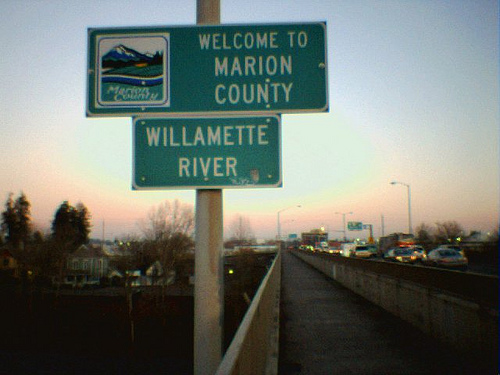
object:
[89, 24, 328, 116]
sign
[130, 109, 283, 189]
sign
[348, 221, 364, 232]
sign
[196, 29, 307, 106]
writing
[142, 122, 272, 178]
writing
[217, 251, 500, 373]
bridge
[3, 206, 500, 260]
horizon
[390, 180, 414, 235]
street light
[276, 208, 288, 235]
street light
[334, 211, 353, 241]
street light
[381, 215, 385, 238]
street light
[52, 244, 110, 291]
house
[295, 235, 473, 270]
cars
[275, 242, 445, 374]
sidewalk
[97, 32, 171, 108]
picture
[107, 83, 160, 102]
writing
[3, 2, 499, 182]
sky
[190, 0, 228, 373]
post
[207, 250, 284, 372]
railing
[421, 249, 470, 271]
car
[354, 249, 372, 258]
seda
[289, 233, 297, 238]
sign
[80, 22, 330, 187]
signs